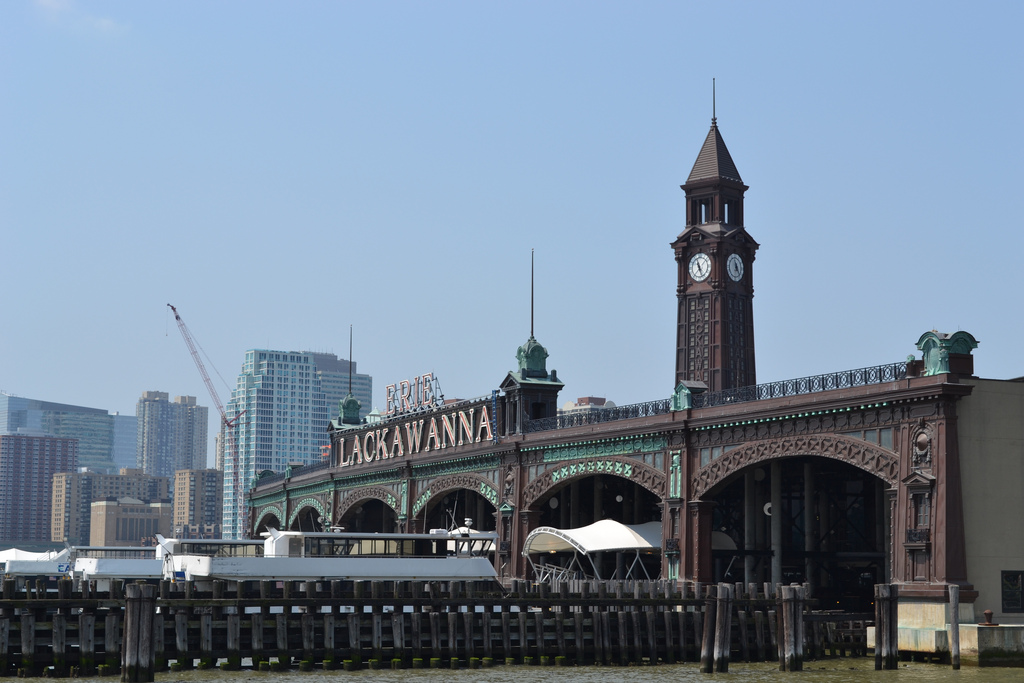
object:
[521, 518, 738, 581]
boat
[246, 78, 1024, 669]
bridge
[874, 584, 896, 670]
posts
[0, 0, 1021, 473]
skies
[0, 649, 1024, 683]
water